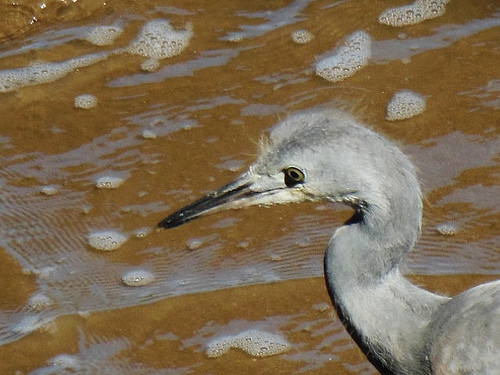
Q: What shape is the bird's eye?
A: Round.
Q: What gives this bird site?
A: Eyes.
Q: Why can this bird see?
A: Eyes.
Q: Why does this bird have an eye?
A: Genetics.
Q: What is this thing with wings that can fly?
A: Bird.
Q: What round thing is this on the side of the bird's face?
A: Eye.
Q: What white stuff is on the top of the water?
A: Foam.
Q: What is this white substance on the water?
A: Foam.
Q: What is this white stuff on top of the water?
A: Foam.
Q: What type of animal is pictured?
A: A bird.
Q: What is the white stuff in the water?
A: Foam.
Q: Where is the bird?
A: Standing in the water.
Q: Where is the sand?
A: Under the water.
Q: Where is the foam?
A: Floating in the water.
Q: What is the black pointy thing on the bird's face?
A: A beak.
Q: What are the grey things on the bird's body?
A: Feathers.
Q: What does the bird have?
A: A eye.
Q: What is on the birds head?
A: Eyes.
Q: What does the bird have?
A: Eyes.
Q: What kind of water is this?
A: Dirty nasty water.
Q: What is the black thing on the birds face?
A: A beak.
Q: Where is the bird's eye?
A: On its face.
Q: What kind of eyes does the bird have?
A: Yellow.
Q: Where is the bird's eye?
A: On the side of its face.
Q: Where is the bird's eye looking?
A: To the left.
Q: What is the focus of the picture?
A: The bird's eye.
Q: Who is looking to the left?
A: The white bird.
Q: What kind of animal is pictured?
A: A bird.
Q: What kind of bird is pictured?
A: A heron.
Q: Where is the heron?
A: Near water.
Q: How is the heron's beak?
A: Very pointy.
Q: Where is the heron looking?
A: Into the water.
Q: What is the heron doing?
A: Hunting.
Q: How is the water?
A: Clean and clear.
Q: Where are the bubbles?
A: On the water.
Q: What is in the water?
A: A bird.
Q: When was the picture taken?
A: Daytime.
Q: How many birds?
A: 1.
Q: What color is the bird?
A: White.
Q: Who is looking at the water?
A: The white bird.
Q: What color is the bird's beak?
A: Black.